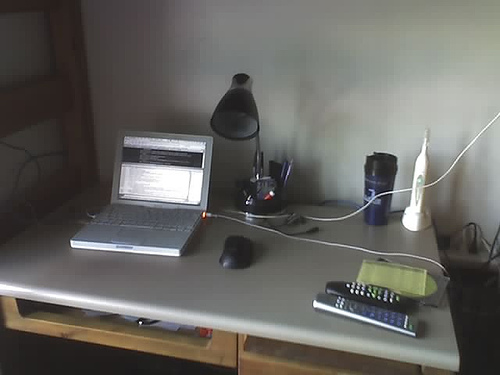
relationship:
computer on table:
[69, 129, 213, 257] [8, 179, 461, 373]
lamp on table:
[211, 66, 285, 211] [8, 179, 461, 373]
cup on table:
[363, 149, 397, 229] [8, 179, 461, 373]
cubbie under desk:
[13, 300, 213, 352] [5, 179, 496, 369]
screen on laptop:
[118, 137, 209, 206] [64, 126, 215, 261]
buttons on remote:
[332, 281, 412, 333] [324, 280, 410, 313]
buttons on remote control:
[332, 281, 412, 333] [312, 296, 419, 338]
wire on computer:
[203, 211, 446, 275] [69, 133, 210, 256]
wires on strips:
[439, 220, 496, 253] [446, 241, 498, 265]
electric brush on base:
[408, 127, 435, 214] [398, 203, 436, 233]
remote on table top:
[324, 280, 416, 313] [0, 182, 460, 371]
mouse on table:
[215, 233, 257, 269] [8, 179, 461, 373]